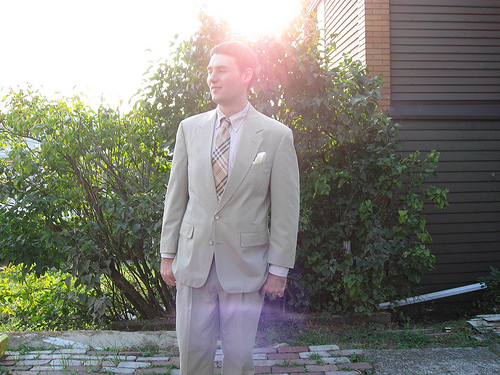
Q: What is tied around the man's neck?
A: A tie.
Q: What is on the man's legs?
A: Pants.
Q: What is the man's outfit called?
A: A suit.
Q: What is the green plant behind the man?
A: Bush.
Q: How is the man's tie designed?
A: Plaid.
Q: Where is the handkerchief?
A: In the man's jacket pocket.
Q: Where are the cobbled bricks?
A: On the ground.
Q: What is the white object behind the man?
A: A metal rail.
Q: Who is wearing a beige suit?
A: The man in the plaid tie.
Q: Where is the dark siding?
A: On the house.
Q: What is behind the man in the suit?
A: A green bush.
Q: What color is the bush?
A: Green.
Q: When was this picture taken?
A: Daytime.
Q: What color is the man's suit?
A: Grey.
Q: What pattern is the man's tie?
A: It is plaid.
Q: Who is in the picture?
A: A man.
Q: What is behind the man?
A: A bush.